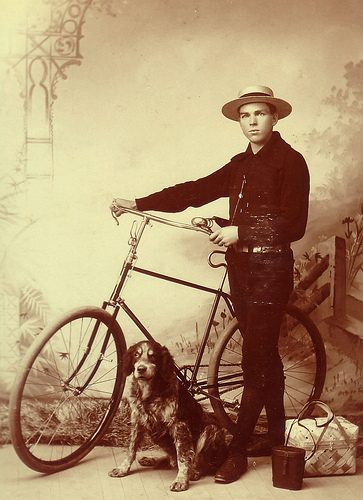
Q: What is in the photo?
A: A dog.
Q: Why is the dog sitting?
A: For photograph.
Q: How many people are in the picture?
A: One.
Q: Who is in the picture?
A: A man.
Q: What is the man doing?
A: Holding a bicycle.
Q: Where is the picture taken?
A: A studio.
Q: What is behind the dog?
A: A bike.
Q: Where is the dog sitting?
A: On the floor.